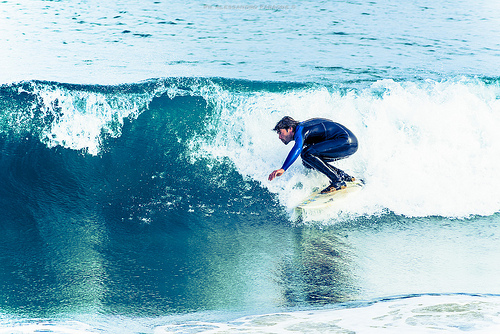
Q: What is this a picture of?
A: A man surfing.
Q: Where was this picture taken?
A: The ocean.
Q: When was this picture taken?
A: During daylight.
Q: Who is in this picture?
A: A male surfer.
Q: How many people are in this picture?
A: One person.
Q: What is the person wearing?
A: A blue wetsuit.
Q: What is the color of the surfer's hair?
A: Brunette.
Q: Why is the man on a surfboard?
A: He is surfing.